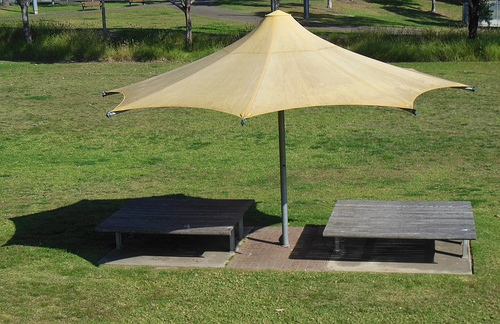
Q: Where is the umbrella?
A: Between benches.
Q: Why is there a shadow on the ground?
A: Sunny.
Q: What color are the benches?
A: Gray.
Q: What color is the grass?
A: Green.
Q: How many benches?
A: Two.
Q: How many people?
A: No people.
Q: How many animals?
A: None.